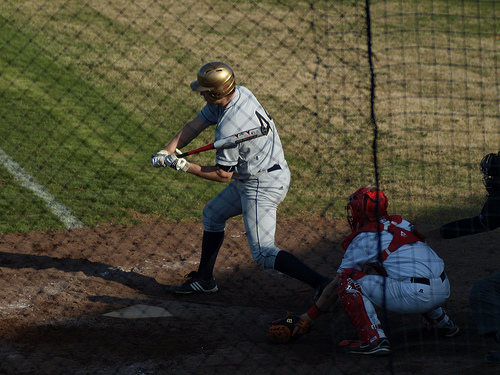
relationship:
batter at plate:
[172, 55, 330, 298] [105, 300, 178, 323]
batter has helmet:
[172, 55, 330, 298] [187, 63, 237, 95]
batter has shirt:
[172, 55, 330, 298] [208, 87, 282, 168]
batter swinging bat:
[172, 55, 330, 298] [173, 123, 273, 157]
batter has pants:
[172, 55, 330, 298] [207, 170, 288, 259]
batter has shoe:
[172, 55, 330, 298] [169, 268, 221, 295]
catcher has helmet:
[313, 187, 460, 345] [358, 181, 385, 220]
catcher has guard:
[313, 187, 460, 345] [346, 193, 362, 232]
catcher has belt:
[313, 187, 460, 345] [405, 271, 453, 285]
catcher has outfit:
[313, 187, 460, 345] [343, 229, 447, 317]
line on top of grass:
[3, 141, 87, 233] [4, 8, 495, 224]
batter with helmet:
[172, 55, 330, 298] [187, 63, 237, 95]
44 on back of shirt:
[255, 103, 275, 132] [208, 87, 282, 168]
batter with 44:
[172, 55, 330, 298] [255, 103, 275, 132]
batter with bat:
[172, 55, 330, 298] [173, 123, 273, 157]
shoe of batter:
[169, 268, 221, 295] [172, 55, 330, 298]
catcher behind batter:
[313, 187, 460, 345] [172, 55, 330, 298]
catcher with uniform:
[313, 187, 460, 345] [343, 229, 447, 317]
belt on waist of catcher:
[405, 271, 453, 285] [313, 187, 460, 345]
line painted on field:
[3, 141, 87, 233] [4, 8, 495, 224]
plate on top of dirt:
[105, 300, 178, 323] [8, 219, 490, 371]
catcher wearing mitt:
[313, 187, 460, 345] [264, 308, 307, 340]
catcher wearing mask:
[313, 187, 460, 345] [341, 196, 361, 228]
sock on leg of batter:
[202, 229, 225, 279] [172, 55, 330, 298]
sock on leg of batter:
[276, 250, 324, 291] [172, 55, 330, 298]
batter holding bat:
[172, 55, 330, 298] [173, 123, 273, 157]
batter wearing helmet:
[172, 55, 330, 298] [187, 63, 237, 95]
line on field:
[3, 141, 87, 233] [4, 8, 495, 224]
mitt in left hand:
[264, 308, 307, 340] [290, 305, 318, 333]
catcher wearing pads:
[313, 187, 460, 345] [338, 277, 380, 341]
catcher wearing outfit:
[313, 187, 460, 345] [343, 229, 447, 317]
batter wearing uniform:
[172, 55, 330, 298] [196, 95, 302, 262]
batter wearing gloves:
[172, 55, 330, 298] [155, 146, 184, 171]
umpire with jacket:
[435, 151, 499, 251] [438, 199, 498, 233]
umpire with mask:
[435, 151, 499, 251] [475, 152, 492, 196]